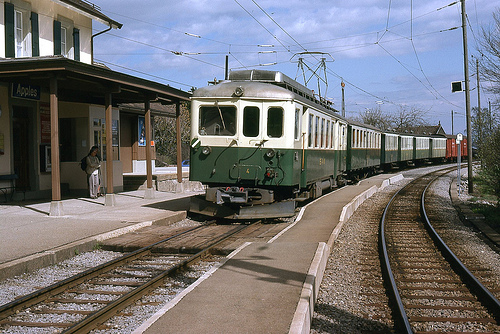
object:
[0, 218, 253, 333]
tracks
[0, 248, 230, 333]
gravel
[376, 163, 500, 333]
train tracks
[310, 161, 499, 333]
gravel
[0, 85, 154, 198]
wall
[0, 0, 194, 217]
building